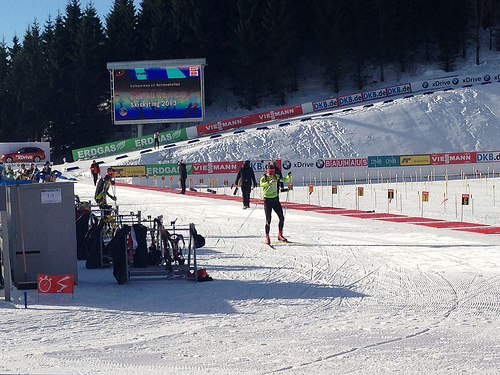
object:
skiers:
[176, 155, 283, 209]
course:
[0, 0, 500, 375]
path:
[0, 239, 499, 375]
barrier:
[128, 153, 500, 223]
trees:
[0, 0, 500, 155]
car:
[0, 146, 47, 163]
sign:
[37, 272, 75, 294]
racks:
[74, 194, 206, 286]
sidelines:
[120, 191, 260, 248]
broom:
[16, 185, 39, 290]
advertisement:
[72, 126, 198, 162]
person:
[260, 163, 294, 245]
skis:
[275, 237, 292, 243]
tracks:
[0, 204, 500, 375]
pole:
[284, 184, 293, 220]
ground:
[0, 178, 500, 375]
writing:
[205, 119, 243, 131]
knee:
[279, 216, 286, 222]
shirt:
[259, 174, 292, 199]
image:
[38, 275, 72, 293]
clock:
[38, 275, 52, 292]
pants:
[240, 182, 250, 205]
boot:
[187, 268, 214, 282]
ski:
[266, 243, 277, 250]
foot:
[265, 234, 271, 243]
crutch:
[110, 177, 120, 215]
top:
[259, 173, 292, 198]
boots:
[264, 228, 287, 244]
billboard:
[107, 56, 207, 137]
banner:
[71, 100, 302, 161]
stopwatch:
[37, 275, 52, 292]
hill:
[124, 65, 500, 189]